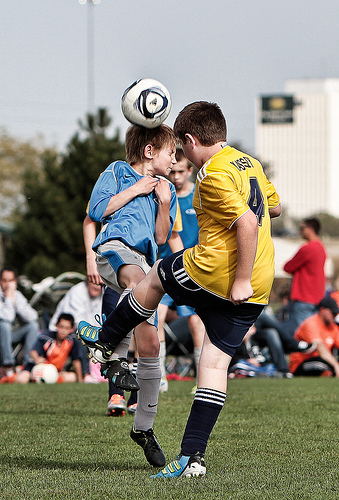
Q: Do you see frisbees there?
A: No, there are no frisbees.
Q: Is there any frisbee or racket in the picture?
A: No, there are no frisbees or rackets.